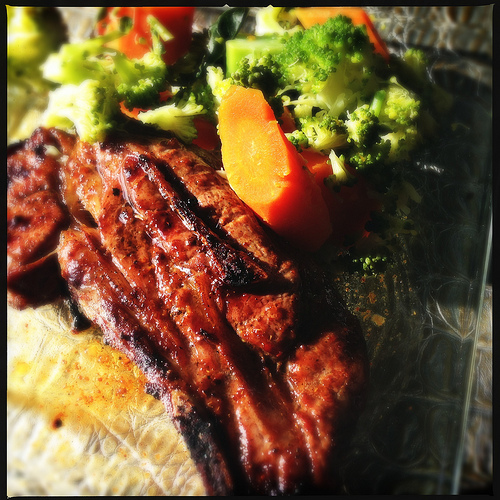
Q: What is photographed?
A: Food.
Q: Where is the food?
A: On a plate.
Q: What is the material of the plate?
A: Glass.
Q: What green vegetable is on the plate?
A: Broccoli.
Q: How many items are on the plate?
A: Three.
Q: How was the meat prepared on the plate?
A: Grilled.